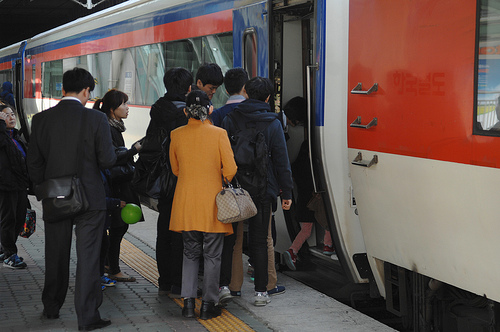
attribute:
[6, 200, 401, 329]
platform — grey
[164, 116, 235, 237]
coat — orange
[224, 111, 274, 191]
backpack — black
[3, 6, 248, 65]
stripes — red, blue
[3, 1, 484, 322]
train — white, red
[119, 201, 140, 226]
ball — green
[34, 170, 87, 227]
bag — black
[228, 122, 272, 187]
bag — black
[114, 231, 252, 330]
stripe — yellow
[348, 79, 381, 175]
hooks — metal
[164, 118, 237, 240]
jacket — yellow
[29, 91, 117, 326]
suit — black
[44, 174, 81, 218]
bag — black, small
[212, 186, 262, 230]
handbag — tan, small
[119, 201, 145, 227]
ball — round, green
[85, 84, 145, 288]
woman — black